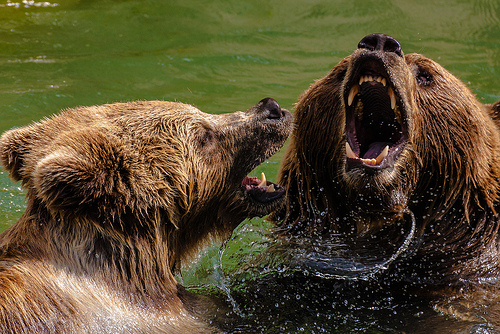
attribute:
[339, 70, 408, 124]
bear's teeth — yellow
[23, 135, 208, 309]
bear's fur — brown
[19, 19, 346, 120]
water — green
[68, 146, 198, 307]
bear's fur — wet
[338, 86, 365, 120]
tooth — sharp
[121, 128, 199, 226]
fur — soft, brown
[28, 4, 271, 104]
river water — smooth, green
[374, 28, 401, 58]
nostrils — big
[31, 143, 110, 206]
ear — fluffy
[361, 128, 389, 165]
tongue — black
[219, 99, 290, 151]
snout — large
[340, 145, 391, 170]
teeth — yellow, sharp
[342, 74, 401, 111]
teeth — yellow, sharp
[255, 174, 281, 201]
teeth — sharp, yellow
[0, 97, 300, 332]
bear — brown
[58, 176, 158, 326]
fur — thick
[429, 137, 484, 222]
fur — brown, thick